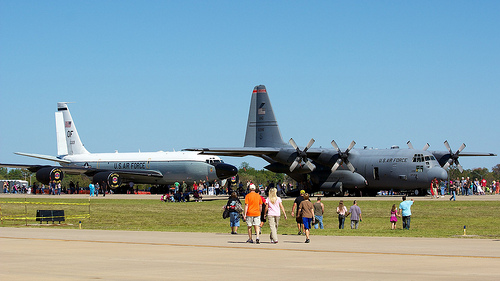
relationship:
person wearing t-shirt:
[243, 183, 264, 245] [243, 192, 264, 218]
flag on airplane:
[65, 122, 73, 129] [14, 102, 238, 195]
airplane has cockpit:
[14, 102, 238, 195] [205, 157, 226, 166]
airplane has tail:
[182, 83, 496, 198] [244, 83, 284, 149]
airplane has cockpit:
[182, 83, 496, 198] [412, 153, 438, 164]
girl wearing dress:
[389, 204, 398, 224] [389, 205, 398, 224]